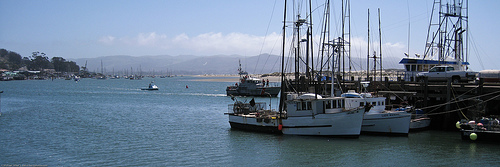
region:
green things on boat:
[455, 115, 478, 144]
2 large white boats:
[223, 87, 414, 148]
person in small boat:
[138, 79, 164, 94]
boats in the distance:
[73, 59, 189, 81]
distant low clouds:
[82, 27, 427, 58]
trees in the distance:
[1, 43, 82, 77]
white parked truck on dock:
[407, 60, 479, 86]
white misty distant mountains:
[65, 46, 415, 73]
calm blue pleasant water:
[1, 80, 471, 165]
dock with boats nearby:
[219, 68, 498, 148]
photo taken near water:
[16, 27, 484, 161]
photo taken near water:
[88, 35, 340, 149]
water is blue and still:
[64, 88, 212, 154]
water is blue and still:
[80, 87, 155, 144]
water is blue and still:
[89, 121, 150, 158]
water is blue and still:
[69, 112, 139, 160]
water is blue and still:
[106, 120, 170, 152]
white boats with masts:
[216, 15, 413, 140]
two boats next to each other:
[220, 55, 415, 141]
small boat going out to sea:
[76, 77, 191, 123]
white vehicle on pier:
[391, 46, 476, 91]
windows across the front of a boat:
[281, 90, 346, 111]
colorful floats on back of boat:
[440, 107, 490, 142]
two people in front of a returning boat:
[220, 46, 280, 96]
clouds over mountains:
[85, 25, 275, 66]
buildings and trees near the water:
[7, 47, 112, 89]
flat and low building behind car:
[388, 46, 478, 82]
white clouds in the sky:
[96, 30, 415, 57]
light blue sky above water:
[83, 8, 140, 25]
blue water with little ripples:
[60, 101, 173, 143]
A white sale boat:
[225, 0, 370, 142]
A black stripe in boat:
[283, 121, 333, 130]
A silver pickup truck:
[414, 62, 481, 85]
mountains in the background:
[57, 51, 409, 76]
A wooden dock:
[281, 79, 499, 130]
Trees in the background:
[0, 46, 82, 73]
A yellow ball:
[467, 131, 479, 141]